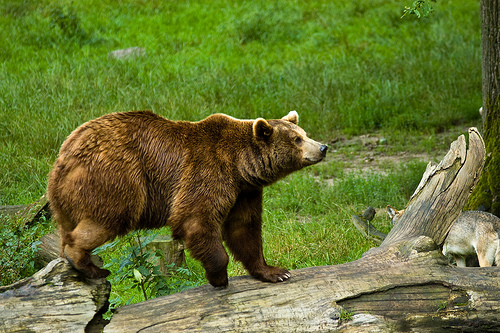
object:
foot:
[248, 264, 293, 283]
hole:
[337, 281, 469, 316]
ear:
[251, 117, 274, 139]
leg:
[63, 215, 128, 266]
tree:
[397, 0, 500, 212]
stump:
[33, 231, 105, 269]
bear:
[46, 109, 332, 288]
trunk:
[0, 254, 110, 331]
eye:
[292, 137, 304, 146]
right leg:
[179, 209, 227, 272]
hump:
[204, 112, 236, 123]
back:
[68, 109, 252, 150]